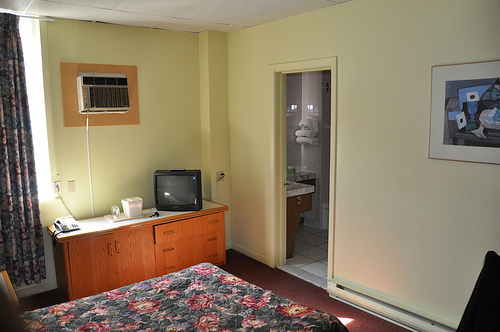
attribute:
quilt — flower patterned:
[16, 250, 341, 330]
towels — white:
[285, 113, 327, 155]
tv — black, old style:
[153, 169, 201, 213]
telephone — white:
[56, 215, 79, 232]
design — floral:
[1, 263, 349, 332]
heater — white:
[329, 275, 457, 332]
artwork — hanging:
[428, 60, 498, 169]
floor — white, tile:
[288, 216, 328, 275]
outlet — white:
[52, 181, 61, 197]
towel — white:
[296, 128, 314, 140]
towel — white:
[300, 136, 317, 145]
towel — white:
[300, 112, 317, 129]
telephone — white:
[51, 213, 79, 235]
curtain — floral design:
[0, 12, 48, 284]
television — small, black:
[151, 168, 203, 210]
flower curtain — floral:
[1, 13, 47, 292]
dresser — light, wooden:
[49, 202, 236, 292]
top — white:
[52, 207, 190, 229]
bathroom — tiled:
[267, 61, 346, 284]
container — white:
[111, 183, 163, 221]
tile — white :
[293, 243, 331, 265]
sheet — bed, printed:
[16, 258, 351, 329]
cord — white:
[53, 197, 80, 220]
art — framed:
[429, 57, 499, 163]